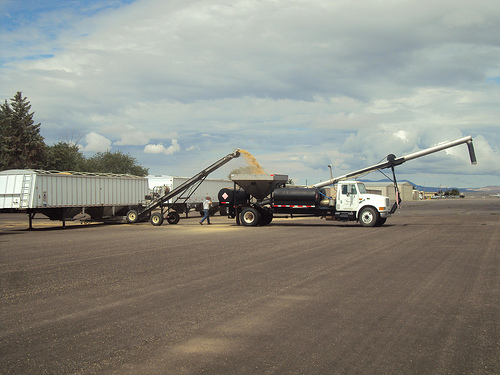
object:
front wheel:
[359, 204, 380, 227]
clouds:
[417, 1, 499, 52]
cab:
[337, 180, 391, 226]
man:
[199, 194, 214, 226]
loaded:
[237, 156, 394, 226]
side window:
[342, 185, 348, 194]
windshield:
[357, 183, 367, 193]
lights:
[379, 207, 387, 211]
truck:
[228, 171, 395, 227]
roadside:
[0, 231, 49, 269]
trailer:
[0, 169, 149, 231]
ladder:
[19, 171, 34, 210]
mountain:
[404, 178, 440, 192]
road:
[405, 201, 500, 373]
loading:
[230, 147, 391, 228]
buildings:
[366, 179, 423, 200]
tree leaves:
[0, 146, 14, 161]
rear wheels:
[240, 207, 259, 227]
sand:
[249, 162, 264, 178]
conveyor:
[134, 147, 240, 226]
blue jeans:
[199, 209, 213, 226]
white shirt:
[203, 200, 210, 210]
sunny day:
[1, 1, 499, 375]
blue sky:
[1, 3, 496, 84]